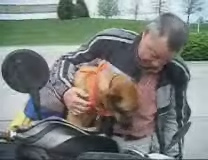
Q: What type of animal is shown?
A: Dog.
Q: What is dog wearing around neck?
A: Scarf.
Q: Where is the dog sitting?
A: Man's lap.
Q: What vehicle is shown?
A: Motorcycle.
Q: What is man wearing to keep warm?
A: Motorcycle jacket.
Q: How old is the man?
A: Middle-aged.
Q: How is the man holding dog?
A: Under arm.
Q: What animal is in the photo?
A: A dog.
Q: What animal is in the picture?
A: Dog.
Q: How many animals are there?
A: One.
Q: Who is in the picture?
A: The man in the wheelchair.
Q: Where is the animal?
A: On the man's lap.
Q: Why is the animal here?
A: It is a service dog.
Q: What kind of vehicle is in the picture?
A: A wheelchair.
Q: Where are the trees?
A: Behind the man.